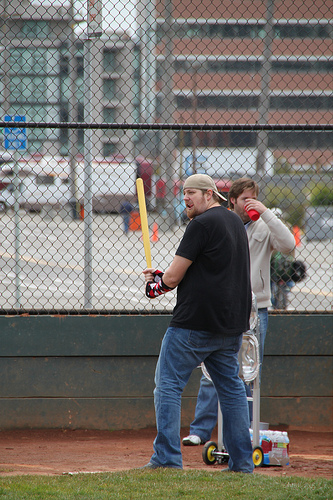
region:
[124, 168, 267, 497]
a large man holding a bat.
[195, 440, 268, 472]
a wheel mechanism on a dolly.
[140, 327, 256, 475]
a pair of blue jeans.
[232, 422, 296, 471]
a package of water bottles.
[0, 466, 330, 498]
a field of green grass.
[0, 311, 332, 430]
a wall with a fence.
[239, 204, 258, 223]
a red drinking cup.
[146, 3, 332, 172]
a brown multi story building.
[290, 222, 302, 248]
an orange cone.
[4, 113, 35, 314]
a blue handicap sign.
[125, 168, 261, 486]
guy holding baseball bat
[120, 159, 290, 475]
handtruck behind man with bat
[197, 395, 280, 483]
yellow wheels on handtruck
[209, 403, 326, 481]
handtruck carrying carton of water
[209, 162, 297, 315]
guy drinking from red cup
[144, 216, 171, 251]
orange cone in roadway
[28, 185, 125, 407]
chain link fence and green boards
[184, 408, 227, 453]
blue jeans and white shoe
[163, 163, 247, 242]
guy wearing tan baseball cap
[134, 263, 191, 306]
black, red, and white gloves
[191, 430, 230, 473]
this is the right wheel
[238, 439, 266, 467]
this is the left wheel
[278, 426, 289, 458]
this is a water bottle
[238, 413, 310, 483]
this is a package of water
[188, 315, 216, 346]
this is the back pocket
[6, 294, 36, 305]
this is the a chain link fence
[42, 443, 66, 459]
this is the brown dirt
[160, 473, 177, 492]
this is green grass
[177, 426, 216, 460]
this is a white shoe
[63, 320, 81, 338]
this is the color green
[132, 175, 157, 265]
a long yellow bat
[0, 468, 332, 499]
a section of green grass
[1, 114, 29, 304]
a blue and white sign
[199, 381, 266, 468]
part of a gray dolly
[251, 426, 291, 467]
a pack of bottled water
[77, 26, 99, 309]
a long gray pole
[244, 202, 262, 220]
a red plastic cup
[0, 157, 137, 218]
a brown and white motorhome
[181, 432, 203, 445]
the shoe of a man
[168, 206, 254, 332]
a man's black t-shirt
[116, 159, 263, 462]
Man holding a yellow bat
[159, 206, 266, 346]
A black t-shirt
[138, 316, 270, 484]
Pair of blue jeans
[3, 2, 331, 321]
Fence behind two people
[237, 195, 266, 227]
A plastic red cup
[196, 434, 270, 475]
Yellow and black wheels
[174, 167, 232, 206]
A beige baseball cap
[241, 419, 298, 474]
Water bottles on the ground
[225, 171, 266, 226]
Man has brown hair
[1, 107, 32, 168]
Blue and white street sign